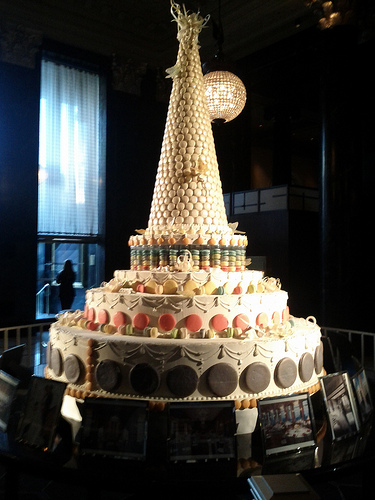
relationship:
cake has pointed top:
[30, 2, 332, 443] [123, 4, 248, 256]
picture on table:
[246, 389, 320, 458] [2, 408, 373, 496]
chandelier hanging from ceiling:
[199, 67, 249, 126] [25, 5, 364, 26]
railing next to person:
[1, 311, 49, 351] [52, 253, 81, 309]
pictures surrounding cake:
[6, 380, 363, 465] [30, 2, 332, 443]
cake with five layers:
[30, 2, 332, 443] [37, 225, 335, 405]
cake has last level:
[30, 2, 332, 443] [119, 227, 250, 271]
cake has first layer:
[30, 2, 332, 443] [49, 329, 305, 387]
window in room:
[30, 37, 107, 297] [5, 4, 374, 500]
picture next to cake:
[246, 389, 320, 458] [30, 2, 332, 443]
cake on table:
[30, 2, 332, 443] [2, 408, 373, 496]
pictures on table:
[6, 380, 363, 465] [2, 408, 373, 496]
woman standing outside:
[52, 253, 81, 309] [41, 218, 97, 308]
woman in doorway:
[52, 253, 81, 309] [41, 218, 97, 308]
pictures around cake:
[6, 380, 363, 465] [30, 2, 332, 443]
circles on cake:
[156, 278, 215, 295] [30, 2, 332, 443]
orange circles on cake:
[133, 309, 229, 330] [30, 2, 332, 443]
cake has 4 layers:
[30, 2, 332, 443] [37, 225, 335, 405]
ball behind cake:
[199, 67, 249, 126] [30, 2, 332, 443]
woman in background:
[52, 253, 81, 309] [16, 200, 121, 270]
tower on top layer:
[123, 4, 248, 256] [119, 227, 250, 271]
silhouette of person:
[52, 253, 81, 309] [58, 252, 85, 324]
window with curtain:
[36, 135, 97, 284] [30, 37, 107, 297]